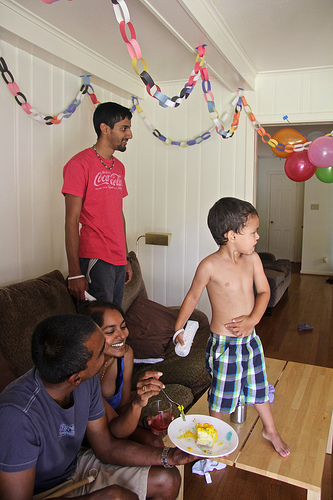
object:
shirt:
[0, 368, 107, 494]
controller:
[175, 320, 199, 356]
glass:
[147, 396, 172, 437]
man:
[61, 101, 133, 313]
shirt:
[61, 143, 130, 267]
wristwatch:
[158, 445, 169, 472]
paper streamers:
[111, 1, 204, 108]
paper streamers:
[203, 44, 243, 139]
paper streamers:
[2, 58, 89, 126]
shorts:
[205, 328, 270, 413]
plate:
[167, 414, 238, 460]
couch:
[0, 251, 212, 500]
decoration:
[309, 136, 333, 168]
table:
[161, 354, 331, 500]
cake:
[194, 422, 218, 447]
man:
[0, 313, 201, 499]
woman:
[89, 302, 165, 436]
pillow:
[122, 249, 142, 313]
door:
[260, 144, 308, 269]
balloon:
[271, 128, 307, 159]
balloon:
[284, 149, 316, 181]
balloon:
[308, 135, 333, 168]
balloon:
[315, 165, 332, 185]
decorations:
[0, 4, 327, 156]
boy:
[172, 196, 290, 457]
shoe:
[294, 324, 312, 335]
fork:
[160, 389, 186, 421]